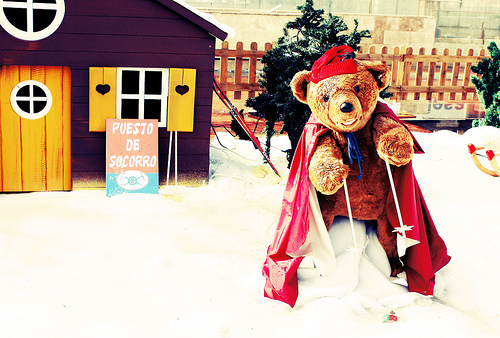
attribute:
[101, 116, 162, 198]
sign — written in Spanish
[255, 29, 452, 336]
bear — big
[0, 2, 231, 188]
house — purple, toy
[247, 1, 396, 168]
tree — green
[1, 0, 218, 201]
playhouse — purple, yellow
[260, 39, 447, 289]
bear — brown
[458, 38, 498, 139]
tree — green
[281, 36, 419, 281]
teddy bear — wearing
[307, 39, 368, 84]
hat — red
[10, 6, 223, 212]
playhouse — purple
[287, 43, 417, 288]
bear — standing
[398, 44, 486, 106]
fence — picket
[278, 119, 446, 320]
cape — red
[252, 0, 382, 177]
tree — green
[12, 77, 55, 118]
window — circle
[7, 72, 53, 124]
window — circle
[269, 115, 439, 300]
cloak — red